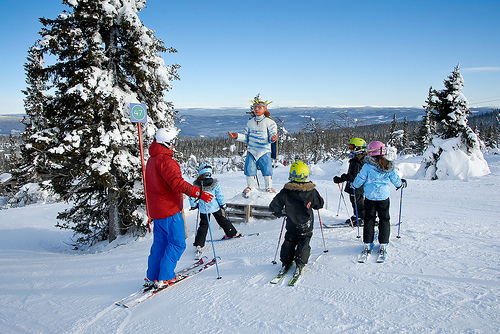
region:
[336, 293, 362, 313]
Small patch of white snow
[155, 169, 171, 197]
Red jacket of the skier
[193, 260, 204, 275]
Left and right ski of skier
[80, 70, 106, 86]
Snow on the Christmas tree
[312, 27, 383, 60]
A clear blue sky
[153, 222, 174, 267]
Blue pants of the skier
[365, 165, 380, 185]
Light blue sweater of girl skier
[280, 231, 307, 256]
Black pants of skier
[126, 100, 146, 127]
Sign that says 47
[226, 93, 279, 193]
Statue of a person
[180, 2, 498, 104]
clear blue of daytime sky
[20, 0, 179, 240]
snow covered pine tree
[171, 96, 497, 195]
blue valley on horizon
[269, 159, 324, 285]
child in yellow helmet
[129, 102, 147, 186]
sign on red pole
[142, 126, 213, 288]
perosn in red coat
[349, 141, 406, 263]
back of child on skis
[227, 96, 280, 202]
statue on snowy mound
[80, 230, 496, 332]
ski marks in snow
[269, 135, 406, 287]
three children on skis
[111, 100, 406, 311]
Group of people preparing to ski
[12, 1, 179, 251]
Snow covered evergreen tree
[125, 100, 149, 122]
Blue, white and yellow 47 sign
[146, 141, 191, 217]
Red snow coat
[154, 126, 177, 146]
White skiing helmet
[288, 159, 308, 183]
Yellow skiing helmet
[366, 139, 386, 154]
Pink skiing helmet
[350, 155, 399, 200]
Blue snow coat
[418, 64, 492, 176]
Tree with a lot of snow at base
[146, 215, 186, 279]
Bright blue pair of pants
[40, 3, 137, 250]
Pine tree covered in snow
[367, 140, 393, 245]
Girl with blue jacket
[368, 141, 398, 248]
Girl with pink helmet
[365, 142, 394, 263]
Girl in black pants on skis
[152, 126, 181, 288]
Adult in red coat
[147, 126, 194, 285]
Adult in blue pants on skis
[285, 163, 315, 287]
Child in yellow helmet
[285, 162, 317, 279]
Child in black coat and pants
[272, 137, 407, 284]
Three children in helmets on skis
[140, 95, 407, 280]
Group of people learning to ski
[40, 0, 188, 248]
small green tree covered with snow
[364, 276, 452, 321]
ground covered with white snow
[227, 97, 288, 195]
statue on a mountain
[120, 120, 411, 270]
one adult and four children looking at statue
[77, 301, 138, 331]
track marks in snow from skis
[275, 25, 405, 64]
clear blue sky with no clouds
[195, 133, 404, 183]
all four children wearing safety helmets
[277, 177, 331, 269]
child with black ski pants and black ski jacket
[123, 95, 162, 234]
red pole with a green and white sign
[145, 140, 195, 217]
red puffy winter jacket